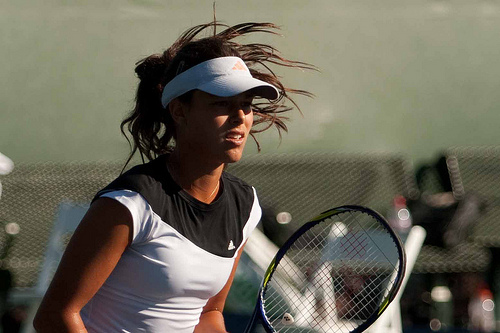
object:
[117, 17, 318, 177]
brown hair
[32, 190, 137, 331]
arm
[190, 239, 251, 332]
arm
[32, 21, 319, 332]
girl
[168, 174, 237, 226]
collar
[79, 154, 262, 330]
shirt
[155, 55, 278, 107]
cap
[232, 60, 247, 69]
orange symbol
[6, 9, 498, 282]
wall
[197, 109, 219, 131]
light skinned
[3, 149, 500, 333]
fence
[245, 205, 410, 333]
racket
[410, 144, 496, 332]
people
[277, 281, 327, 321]
dampener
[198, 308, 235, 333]
woman's hand